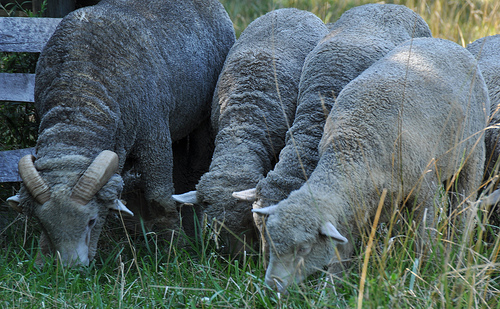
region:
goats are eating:
[1, 0, 484, 299]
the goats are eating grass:
[1, 10, 496, 302]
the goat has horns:
[14, 143, 121, 206]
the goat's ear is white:
[229, 184, 273, 218]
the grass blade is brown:
[356, 164, 381, 307]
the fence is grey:
[1, 17, 86, 204]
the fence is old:
[0, 4, 90, 218]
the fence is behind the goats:
[0, 0, 73, 189]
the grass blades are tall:
[251, 4, 441, 285]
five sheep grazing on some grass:
[1, 2, 499, 305]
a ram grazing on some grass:
[6, 4, 241, 296]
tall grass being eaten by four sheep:
[15, 131, 485, 304]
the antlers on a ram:
[11, 139, 124, 213]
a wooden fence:
[1, 20, 48, 207]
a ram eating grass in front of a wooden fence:
[1, 1, 207, 306]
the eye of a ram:
[78, 212, 101, 234]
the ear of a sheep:
[316, 215, 349, 250]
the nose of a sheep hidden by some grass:
[257, 275, 294, 305]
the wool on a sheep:
[94, 17, 192, 97]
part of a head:
[278, 204, 300, 244]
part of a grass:
[371, 235, 407, 274]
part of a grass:
[373, 245, 418, 298]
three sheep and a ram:
[18, 5, 495, 300]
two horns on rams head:
[3, 146, 147, 239]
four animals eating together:
[6, 16, 497, 304]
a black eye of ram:
[86, 216, 98, 231]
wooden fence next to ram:
[4, 14, 121, 240]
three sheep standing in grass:
[206, 11, 497, 286]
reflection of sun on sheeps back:
[390, 47, 437, 92]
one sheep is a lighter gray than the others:
[273, 49, 499, 289]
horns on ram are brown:
[9, 138, 143, 218]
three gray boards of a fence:
[3, 8, 123, 213]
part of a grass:
[191, 249, 227, 297]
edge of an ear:
[181, 192, 197, 209]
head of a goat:
[39, 180, 72, 232]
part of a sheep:
[203, 159, 228, 199]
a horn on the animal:
[76, 159, 114, 196]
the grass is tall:
[149, 239, 216, 294]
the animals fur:
[351, 94, 396, 128]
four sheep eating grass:
[23, 5, 489, 270]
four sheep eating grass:
[27, 16, 482, 274]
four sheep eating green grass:
[35, 5, 485, 280]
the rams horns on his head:
[5, 141, 131, 223]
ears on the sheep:
[171, 175, 276, 201]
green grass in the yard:
[387, 232, 448, 300]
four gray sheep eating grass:
[70, 30, 421, 300]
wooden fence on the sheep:
[0, 12, 50, 57]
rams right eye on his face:
[76, 206, 101, 229]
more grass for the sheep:
[112, 262, 223, 302]